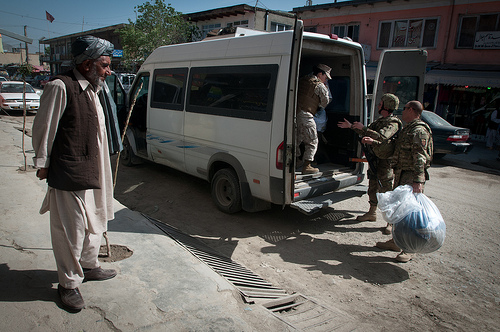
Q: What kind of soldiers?
A: Americans.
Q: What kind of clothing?
A: Ethnic.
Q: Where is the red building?
A: Behind the white van.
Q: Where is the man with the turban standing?
A: On the sidewalk.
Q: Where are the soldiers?
A: Behind the white van.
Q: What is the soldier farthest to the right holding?
A: A clear trash bag.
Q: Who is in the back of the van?
A: A soldier.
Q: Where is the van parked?
A: In the road.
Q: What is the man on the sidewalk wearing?
A: A brown vest.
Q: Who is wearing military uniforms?
A: The men behind the van.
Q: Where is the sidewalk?
A: Next to the road.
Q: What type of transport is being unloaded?
A: A van.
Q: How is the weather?
A: Clear blue skies.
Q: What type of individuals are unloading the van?
A: Soldiers.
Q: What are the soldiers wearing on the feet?
A: Combat boots.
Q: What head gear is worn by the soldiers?
A: Helmets.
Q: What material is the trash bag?
A: White plastic.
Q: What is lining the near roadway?
A: Metal grills.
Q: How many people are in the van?
A: One.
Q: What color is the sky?
A: Blue.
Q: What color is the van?
A: White.